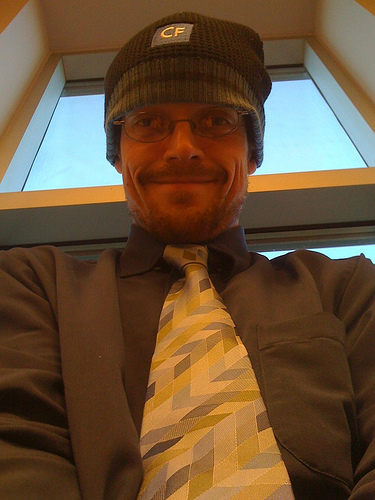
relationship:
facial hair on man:
[122, 160, 255, 248] [1, 13, 373, 496]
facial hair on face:
[122, 160, 255, 248] [113, 94, 254, 237]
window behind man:
[17, 64, 374, 261] [1, 13, 373, 496]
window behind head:
[17, 64, 374, 261] [103, 11, 271, 244]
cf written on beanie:
[162, 27, 195, 43] [104, 11, 273, 168]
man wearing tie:
[1, 13, 373, 496] [138, 263, 295, 496]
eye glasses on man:
[113, 110, 250, 143] [1, 13, 373, 496]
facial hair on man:
[128, 160, 244, 242] [1, 13, 373, 496]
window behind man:
[22, 66, 374, 263] [1, 13, 373, 496]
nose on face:
[158, 113, 207, 165] [99, 101, 265, 247]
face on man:
[99, 101, 265, 247] [1, 13, 373, 496]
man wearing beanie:
[0, 13, 375, 500] [90, 8, 276, 174]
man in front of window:
[1, 13, 373, 496] [17, 64, 374, 261]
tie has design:
[138, 263, 295, 496] [170, 369, 257, 485]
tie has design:
[138, 263, 295, 496] [145, 359, 263, 413]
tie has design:
[138, 263, 295, 496] [143, 327, 234, 411]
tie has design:
[138, 263, 295, 496] [156, 271, 215, 340]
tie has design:
[138, 263, 295, 496] [142, 399, 274, 499]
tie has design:
[138, 263, 295, 496] [164, 244, 209, 265]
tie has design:
[138, 263, 295, 496] [137, 243, 295, 500]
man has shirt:
[1, 13, 373, 496] [0, 219, 373, 498]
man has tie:
[1, 13, 373, 496] [138, 263, 295, 496]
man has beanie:
[0, 13, 375, 500] [104, 11, 273, 168]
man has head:
[0, 13, 375, 500] [103, 64, 274, 274]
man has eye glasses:
[1, 13, 373, 496] [109, 101, 250, 143]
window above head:
[17, 64, 374, 261] [103, 11, 271, 244]